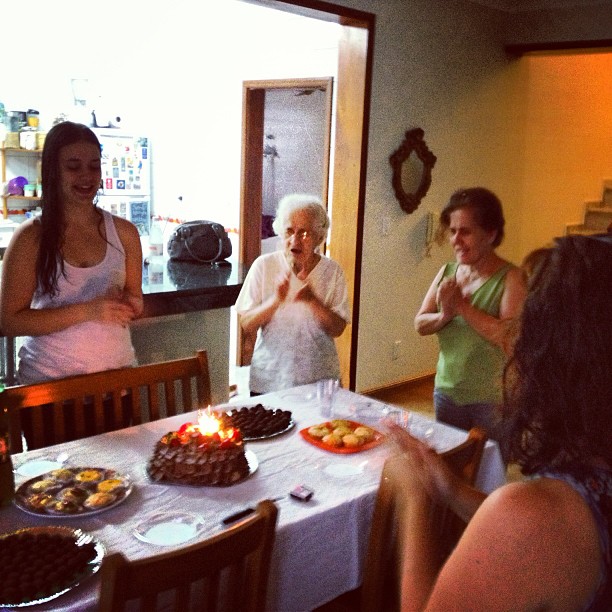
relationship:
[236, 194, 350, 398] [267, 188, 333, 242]
person has hair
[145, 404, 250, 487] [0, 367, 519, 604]
birthday cake on table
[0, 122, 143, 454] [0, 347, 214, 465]
person behind bench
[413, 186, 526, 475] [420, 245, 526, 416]
person has shirt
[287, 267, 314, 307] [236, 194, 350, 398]
hand of person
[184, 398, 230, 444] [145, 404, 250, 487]
candle on birthday cake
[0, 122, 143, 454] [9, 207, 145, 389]
person wearing shirt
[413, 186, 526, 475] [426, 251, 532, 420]
person wearing shirt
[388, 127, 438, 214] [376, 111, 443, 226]
frame with frame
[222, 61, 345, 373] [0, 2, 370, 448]
doorway off kitchen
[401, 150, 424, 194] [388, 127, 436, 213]
picture in frame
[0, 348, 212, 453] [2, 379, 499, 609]
bench around table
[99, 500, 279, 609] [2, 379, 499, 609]
chair around table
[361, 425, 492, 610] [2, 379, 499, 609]
chair around table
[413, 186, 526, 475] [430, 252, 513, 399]
person wearing top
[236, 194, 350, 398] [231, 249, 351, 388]
person wearing shirt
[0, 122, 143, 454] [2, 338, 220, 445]
person standing behind bench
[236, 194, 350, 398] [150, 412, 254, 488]
person standing by birthday cake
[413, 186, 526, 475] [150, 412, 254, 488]
person standing by birthday cake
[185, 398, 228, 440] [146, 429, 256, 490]
candle on birthday cake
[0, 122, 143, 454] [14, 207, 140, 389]
person wearing shirt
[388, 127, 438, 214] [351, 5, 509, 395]
frame on wall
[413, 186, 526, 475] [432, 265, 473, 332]
person holding together hands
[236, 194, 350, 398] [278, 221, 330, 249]
person wearing glasses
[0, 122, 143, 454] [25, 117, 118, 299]
person has hair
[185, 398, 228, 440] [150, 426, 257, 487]
candle on top of cake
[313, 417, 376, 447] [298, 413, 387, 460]
cookies on top of plate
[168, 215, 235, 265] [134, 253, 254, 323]
purse on counter top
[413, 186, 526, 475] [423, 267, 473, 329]
person holding together hands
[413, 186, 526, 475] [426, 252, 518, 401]
person wearing shirt